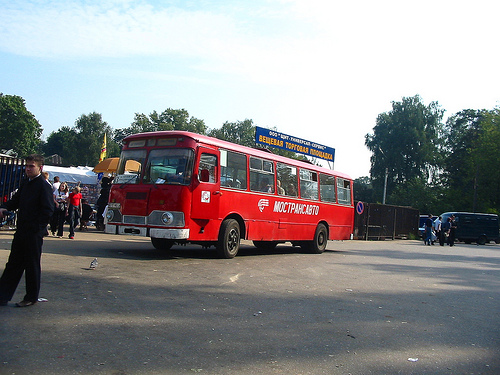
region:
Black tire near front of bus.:
[223, 218, 240, 244]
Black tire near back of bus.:
[306, 228, 334, 247]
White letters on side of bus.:
[268, 198, 341, 221]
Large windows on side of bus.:
[221, 159, 332, 191]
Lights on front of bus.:
[95, 204, 192, 223]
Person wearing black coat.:
[13, 190, 58, 208]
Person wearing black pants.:
[11, 232, 53, 269]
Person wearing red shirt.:
[68, 190, 101, 209]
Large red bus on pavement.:
[121, 135, 373, 275]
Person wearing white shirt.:
[435, 218, 452, 233]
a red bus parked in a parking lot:
[103, 131, 358, 256]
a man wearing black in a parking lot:
[0, 154, 55, 311]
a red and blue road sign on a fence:
[354, 200, 364, 215]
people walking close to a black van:
[424, 213, 459, 248]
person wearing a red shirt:
[67, 189, 83, 207]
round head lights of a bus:
[103, 210, 172, 227]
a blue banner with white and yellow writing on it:
[251, 127, 337, 164]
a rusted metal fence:
[353, 198, 420, 240]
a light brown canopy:
[93, 157, 139, 174]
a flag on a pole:
[99, 132, 107, 162]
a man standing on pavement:
[3, 149, 59, 320]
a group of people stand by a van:
[418, 208, 499, 245]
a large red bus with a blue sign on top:
[98, 124, 370, 263]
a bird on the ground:
[85, 254, 102, 271]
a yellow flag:
[96, 130, 113, 168]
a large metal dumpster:
[339, 198, 426, 245]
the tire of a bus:
[211, 215, 245, 259]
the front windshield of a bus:
[118, 145, 198, 188]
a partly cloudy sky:
[2, 3, 173, 89]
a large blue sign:
[249, 120, 344, 166]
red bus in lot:
[103, 131, 356, 251]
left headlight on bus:
[155, 207, 176, 227]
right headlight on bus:
[97, 207, 115, 222]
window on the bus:
[150, 150, 186, 182]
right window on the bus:
[121, 149, 146, 183]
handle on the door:
[211, 189, 223, 199]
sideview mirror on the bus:
[197, 167, 212, 187]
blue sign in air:
[253, 129, 338, 156]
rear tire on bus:
[311, 222, 331, 252]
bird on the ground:
[80, 255, 101, 273]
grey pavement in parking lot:
[285, 278, 458, 346]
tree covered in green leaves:
[353, 81, 438, 164]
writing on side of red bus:
[267, 197, 326, 227]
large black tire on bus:
[207, 212, 247, 259]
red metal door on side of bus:
[188, 142, 230, 229]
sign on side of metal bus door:
[196, 187, 215, 206]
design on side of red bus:
[249, 191, 274, 222]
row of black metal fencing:
[365, 200, 413, 250]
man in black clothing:
[1, 148, 51, 333]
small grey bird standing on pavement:
[78, 253, 117, 280]